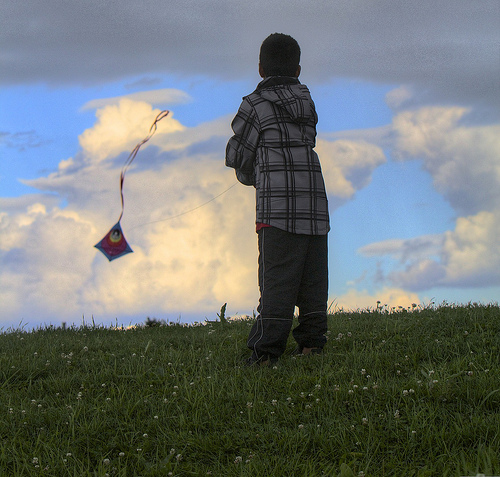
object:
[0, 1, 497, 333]
sky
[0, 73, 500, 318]
cloud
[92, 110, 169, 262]
kite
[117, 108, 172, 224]
strings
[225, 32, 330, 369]
boy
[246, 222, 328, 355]
jeans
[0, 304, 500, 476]
hillside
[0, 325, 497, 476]
flowers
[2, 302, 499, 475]
grass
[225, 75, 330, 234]
hoodie